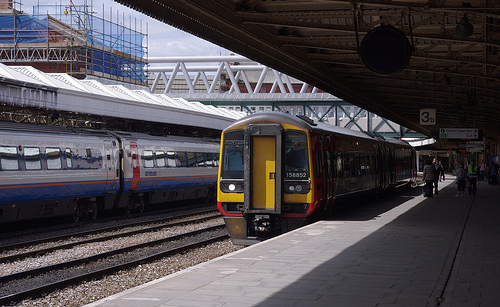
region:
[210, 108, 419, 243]
a train car parked in a station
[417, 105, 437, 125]
a sign overhead that says 3b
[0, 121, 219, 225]
a silver and blue train on the tracks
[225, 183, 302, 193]
round headlights on the front of the yellow train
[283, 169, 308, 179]
a number on the front of the train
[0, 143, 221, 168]
reflections in the train windows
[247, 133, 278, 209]
a yellow door on the front of the train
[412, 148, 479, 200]
people waiting to get on the train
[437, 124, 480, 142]
a location sign hanging from the ceiling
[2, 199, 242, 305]
gravel around the train tracks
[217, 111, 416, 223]
Train in station near platform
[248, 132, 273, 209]
A yellow door on a train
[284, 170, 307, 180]
White numbers on a train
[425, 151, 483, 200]
People on a train platform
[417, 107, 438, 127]
A number three on a sign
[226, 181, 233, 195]
Headlight on a train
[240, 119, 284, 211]
Black frame around a train door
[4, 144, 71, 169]
Windows on the side of a train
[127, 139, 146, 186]
Red painted strip on a train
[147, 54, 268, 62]
White pipe across train tracks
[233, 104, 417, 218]
yellow train at station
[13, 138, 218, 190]
blue and white train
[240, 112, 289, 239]
yellow door on train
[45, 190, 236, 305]
train on black tracks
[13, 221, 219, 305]
grey ballast near tracks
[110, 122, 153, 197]
red stripe on train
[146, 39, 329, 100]
white bridge over train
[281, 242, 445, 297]
platform is light grey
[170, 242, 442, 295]
platform is grey stone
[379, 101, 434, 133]
black number near train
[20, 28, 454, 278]
this is a train station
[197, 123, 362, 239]
the train is yellow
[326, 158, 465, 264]
this is a train stop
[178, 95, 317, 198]
this is a metro train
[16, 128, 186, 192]
this is a passenger train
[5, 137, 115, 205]
the train is silver, blue and red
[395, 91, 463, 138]
the stop number is 3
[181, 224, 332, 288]
the platform is concrete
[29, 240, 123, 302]
these are train tracks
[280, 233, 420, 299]
the platform is gray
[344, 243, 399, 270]
Small section of the gray brick walkway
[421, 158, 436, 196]
Pedestrian walking with a suitcase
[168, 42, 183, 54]
Small patch of the gray cloud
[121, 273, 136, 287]
Small patch of the rocks in the ground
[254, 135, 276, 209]
Back yellow door of the train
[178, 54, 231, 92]
Medium section of the gray bridge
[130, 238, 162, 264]
A pair of train tracks unattended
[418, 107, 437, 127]
Sign indicating station 3b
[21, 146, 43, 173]
Side window on the second train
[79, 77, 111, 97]
White roof of the train station